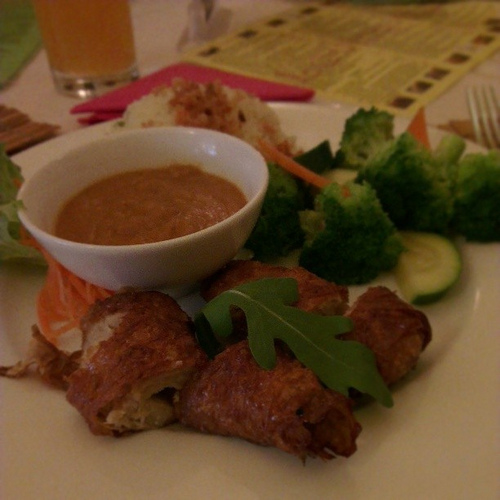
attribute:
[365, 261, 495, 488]
plate — white, round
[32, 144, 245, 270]
bowl — white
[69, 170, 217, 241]
dip — red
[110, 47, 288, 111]
napkin — pink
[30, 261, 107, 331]
carrots — shredded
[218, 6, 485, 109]
menu — yellow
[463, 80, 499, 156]
fork — silver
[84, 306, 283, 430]
dough — fried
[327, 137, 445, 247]
broccoli — green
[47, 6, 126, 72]
beverage — orange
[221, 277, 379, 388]
leaf — green